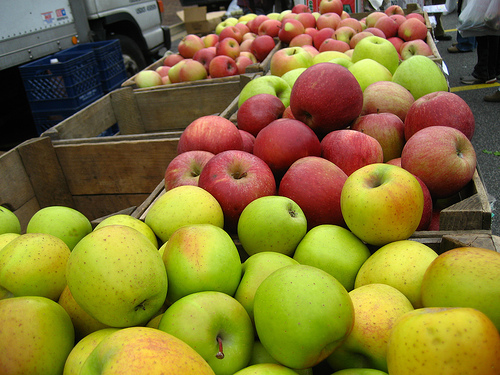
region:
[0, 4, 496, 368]
crates of green and red apples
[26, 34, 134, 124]
blue stacked plastic crates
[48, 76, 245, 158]
empty dark wooden box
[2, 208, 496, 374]
pile of green apples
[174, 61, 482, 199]
pile of red apples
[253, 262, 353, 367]
green apple with reddish spots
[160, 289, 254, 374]
green apple with spots and stem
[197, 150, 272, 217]
red apple with small dark spots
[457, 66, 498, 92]
person wearing grey gym shoe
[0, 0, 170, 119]
parked white truck next to blue crates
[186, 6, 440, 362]
A fruits kept in the tray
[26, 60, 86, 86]
A blue color plastic tray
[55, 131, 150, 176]
Wooden tray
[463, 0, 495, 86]
Peoples standing near the fruit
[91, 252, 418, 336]
Green color fruits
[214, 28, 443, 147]
Red and green color fruits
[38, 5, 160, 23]
Vehicle near the fruits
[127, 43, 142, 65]
Tyre of the Vehicle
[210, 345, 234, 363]
Stem of the fruit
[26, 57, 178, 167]
A blue color plastic tray and wooden tray with fruits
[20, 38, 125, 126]
a stack of blue milk crates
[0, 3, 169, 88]
a white box truck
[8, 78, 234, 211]
two empty wooden crates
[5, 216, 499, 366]
two crates of yellow apples in the foreground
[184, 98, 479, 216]
a case or red apples between two cases of yellow apples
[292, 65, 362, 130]
The top red apple in a pile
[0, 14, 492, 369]
several cases of apples at the market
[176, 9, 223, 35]
brown cardboard box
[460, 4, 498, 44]
plastic shopping bag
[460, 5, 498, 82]
person with black pants and tennis shoes holding the bag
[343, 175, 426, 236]
A fresh looking green apple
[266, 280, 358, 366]
A fresh looking green apple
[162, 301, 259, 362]
A fresh looking green apple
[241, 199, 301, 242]
A fresh looking green apple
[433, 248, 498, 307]
A fresh looking green apple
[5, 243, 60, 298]
A fresh looking green apple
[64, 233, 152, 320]
A fresh looking green apple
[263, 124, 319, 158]
A fresh looking pink apple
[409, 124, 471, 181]
A fresh looking pink apple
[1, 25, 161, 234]
A wooden apple trey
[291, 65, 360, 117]
This apple is red.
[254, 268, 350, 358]
This apple is green.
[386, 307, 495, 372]
This apple is yellow.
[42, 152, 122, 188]
The apple bin is made of wood.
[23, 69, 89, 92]
The crate is blue.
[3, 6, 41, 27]
The side of the truck is white.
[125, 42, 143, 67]
The wheels on the truck are black and silver.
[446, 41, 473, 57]
The man's shoe's are brown.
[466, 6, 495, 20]
The man's shirt is white.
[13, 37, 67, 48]
The side of the truck is metal.